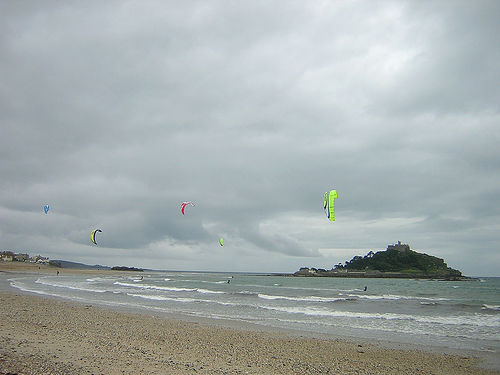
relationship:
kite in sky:
[317, 187, 346, 224] [2, 1, 498, 280]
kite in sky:
[177, 196, 193, 218] [2, 1, 498, 280]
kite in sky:
[215, 234, 236, 253] [2, 1, 498, 280]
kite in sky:
[86, 225, 105, 246] [2, 1, 498, 280]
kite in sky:
[42, 203, 52, 214] [2, 1, 498, 280]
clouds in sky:
[0, 3, 491, 276] [2, 1, 498, 280]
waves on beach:
[14, 270, 494, 355] [1, 275, 499, 374]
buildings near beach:
[1, 248, 52, 266] [1, 275, 499, 374]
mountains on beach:
[297, 239, 468, 280] [1, 275, 499, 374]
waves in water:
[14, 270, 494, 355] [12, 272, 498, 352]